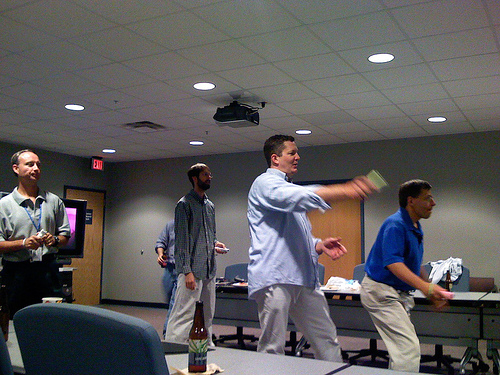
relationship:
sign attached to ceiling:
[91, 158, 103, 168] [3, 9, 498, 165]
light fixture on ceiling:
[364, 51, 394, 66] [6, 3, 490, 130]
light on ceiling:
[64, 103, 85, 111] [3, 9, 498, 165]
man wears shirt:
[376, 202, 446, 282] [365, 208, 425, 291]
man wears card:
[0, 150, 72, 344] [27, 233, 49, 263]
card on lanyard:
[27, 233, 49, 263] [21, 197, 47, 251]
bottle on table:
[153, 281, 245, 368] [164, 336, 413, 374]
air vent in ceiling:
[121, 121, 168, 134] [3, 9, 498, 165]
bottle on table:
[188, 300, 208, 372] [2, 315, 411, 373]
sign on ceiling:
[93, 158, 103, 170] [3, 9, 498, 165]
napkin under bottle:
[181, 365, 212, 374] [188, 300, 208, 372]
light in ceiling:
[365, 35, 422, 95] [3, 9, 498, 165]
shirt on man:
[261, 178, 331, 273] [243, 132, 380, 362]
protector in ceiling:
[201, 83, 268, 133] [3, 9, 498, 165]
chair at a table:
[12, 300, 172, 372] [448, 283, 498, 337]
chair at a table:
[220, 260, 250, 281] [160, 328, 405, 373]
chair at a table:
[312, 259, 326, 286] [448, 283, 498, 337]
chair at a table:
[347, 260, 371, 284] [160, 328, 405, 373]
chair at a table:
[450, 265, 472, 290] [448, 283, 498, 337]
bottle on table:
[188, 300, 208, 372] [185, 245, 498, 352]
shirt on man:
[363, 205, 422, 292] [368, 175, 440, 362]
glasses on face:
[189, 168, 213, 175] [195, 164, 215, 187]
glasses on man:
[189, 168, 213, 175] [163, 163, 230, 348]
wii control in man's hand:
[212, 243, 233, 255] [210, 238, 229, 257]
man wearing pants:
[243, 132, 380, 362] [250, 282, 345, 362]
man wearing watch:
[2, 150, 70, 349] [46, 233, 60, 250]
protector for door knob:
[137, 249, 147, 258] [59, 252, 65, 258]